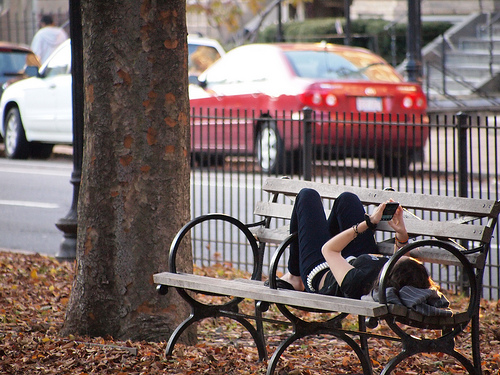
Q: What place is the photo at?
A: It is at the street.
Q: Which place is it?
A: It is a street.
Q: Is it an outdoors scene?
A: Yes, it is outdoors.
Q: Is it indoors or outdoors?
A: It is outdoors.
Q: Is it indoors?
A: No, it is outdoors.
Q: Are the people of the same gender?
A: No, they are both male and female.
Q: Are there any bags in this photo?
A: No, there are no bags.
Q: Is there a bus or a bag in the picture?
A: No, there are no bags or buses.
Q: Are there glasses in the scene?
A: No, there are no glasses.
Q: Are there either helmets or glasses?
A: No, there are no glasses or helmets.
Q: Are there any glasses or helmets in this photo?
A: No, there are no glasses or helmets.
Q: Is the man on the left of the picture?
A: Yes, the man is on the left of the image.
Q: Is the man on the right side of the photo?
A: No, the man is on the left of the image.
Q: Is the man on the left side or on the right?
A: The man is on the left of the image.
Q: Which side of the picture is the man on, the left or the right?
A: The man is on the left of the image.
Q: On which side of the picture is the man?
A: The man is on the left of the image.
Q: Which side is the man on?
A: The man is on the left of the image.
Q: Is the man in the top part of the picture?
A: Yes, the man is in the top of the image.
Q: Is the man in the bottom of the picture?
A: No, the man is in the top of the image.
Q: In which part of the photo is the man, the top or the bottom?
A: The man is in the top of the image.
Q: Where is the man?
A: The man is on the sidewalk.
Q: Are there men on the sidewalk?
A: Yes, there is a man on the sidewalk.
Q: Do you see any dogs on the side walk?
A: No, there is a man on the side walk.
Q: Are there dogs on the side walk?
A: No, there is a man on the side walk.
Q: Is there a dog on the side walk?
A: No, there is a man on the side walk.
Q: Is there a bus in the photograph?
A: No, there are no buses.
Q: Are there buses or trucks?
A: No, there are no buses or trucks.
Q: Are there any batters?
A: No, there are no batters.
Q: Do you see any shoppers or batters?
A: No, there are no batters or shoppers.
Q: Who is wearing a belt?
A: The girl is wearing a belt.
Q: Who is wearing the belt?
A: The girl is wearing a belt.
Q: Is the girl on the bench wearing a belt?
A: Yes, the girl is wearing a belt.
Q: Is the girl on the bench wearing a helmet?
A: No, the girl is wearing a belt.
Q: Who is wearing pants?
A: The girl is wearing pants.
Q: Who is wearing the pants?
A: The girl is wearing pants.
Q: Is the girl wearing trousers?
A: Yes, the girl is wearing trousers.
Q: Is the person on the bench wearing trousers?
A: Yes, the girl is wearing trousers.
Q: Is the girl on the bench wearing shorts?
A: No, the girl is wearing trousers.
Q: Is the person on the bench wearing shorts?
A: No, the girl is wearing trousers.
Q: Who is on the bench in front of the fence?
A: The girl is on the bench.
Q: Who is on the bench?
A: The girl is on the bench.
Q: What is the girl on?
A: The girl is on the bench.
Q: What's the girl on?
A: The girl is on the bench.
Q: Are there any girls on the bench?
A: Yes, there is a girl on the bench.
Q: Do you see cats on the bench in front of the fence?
A: No, there is a girl on the bench.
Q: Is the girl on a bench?
A: Yes, the girl is on a bench.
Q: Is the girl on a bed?
A: No, the girl is on a bench.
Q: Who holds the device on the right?
A: The girl holds the cell phone.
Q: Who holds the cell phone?
A: The girl holds the cell phone.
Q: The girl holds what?
A: The girl holds the cellphone.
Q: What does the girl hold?
A: The girl holds the cellphone.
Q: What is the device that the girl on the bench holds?
A: The device is a cell phone.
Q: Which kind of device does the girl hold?
A: The girl holds the mobile phone.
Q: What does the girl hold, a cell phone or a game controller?
A: The girl holds a cell phone.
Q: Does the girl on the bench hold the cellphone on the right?
A: Yes, the girl holds the cellphone.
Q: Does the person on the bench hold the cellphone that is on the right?
A: Yes, the girl holds the cellphone.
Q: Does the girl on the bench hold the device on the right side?
A: Yes, the girl holds the cellphone.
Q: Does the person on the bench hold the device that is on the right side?
A: Yes, the girl holds the cellphone.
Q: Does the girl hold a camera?
A: No, the girl holds the cellphone.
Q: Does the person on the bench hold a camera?
A: No, the girl holds the cellphone.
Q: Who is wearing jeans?
A: The girl is wearing jeans.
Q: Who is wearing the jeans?
A: The girl is wearing jeans.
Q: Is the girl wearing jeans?
A: Yes, the girl is wearing jeans.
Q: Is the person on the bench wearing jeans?
A: Yes, the girl is wearing jeans.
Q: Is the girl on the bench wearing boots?
A: No, the girl is wearing jeans.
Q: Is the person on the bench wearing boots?
A: No, the girl is wearing jeans.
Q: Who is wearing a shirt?
A: The girl is wearing a shirt.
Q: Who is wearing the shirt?
A: The girl is wearing a shirt.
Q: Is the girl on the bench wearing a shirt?
A: Yes, the girl is wearing a shirt.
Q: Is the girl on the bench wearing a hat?
A: No, the girl is wearing a shirt.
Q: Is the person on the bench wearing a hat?
A: No, the girl is wearing a shirt.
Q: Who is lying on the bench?
A: The girl is lying on the bench.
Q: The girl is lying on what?
A: The girl is lying on the bench.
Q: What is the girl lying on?
A: The girl is lying on the bench.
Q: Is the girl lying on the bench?
A: Yes, the girl is lying on the bench.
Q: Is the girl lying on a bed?
A: No, the girl is lying on the bench.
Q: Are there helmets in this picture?
A: No, there are no helmets.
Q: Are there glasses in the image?
A: No, there are no glasses.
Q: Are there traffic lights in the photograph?
A: No, there are no traffic lights.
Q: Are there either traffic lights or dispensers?
A: No, there are no traffic lights or dispensers.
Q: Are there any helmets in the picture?
A: No, there are no helmets.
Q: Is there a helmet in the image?
A: No, there are no helmets.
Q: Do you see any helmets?
A: No, there are no helmets.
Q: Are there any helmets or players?
A: No, there are no helmets or players.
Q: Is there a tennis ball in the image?
A: No, there are no tennis balls.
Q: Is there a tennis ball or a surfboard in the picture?
A: No, there are no tennis balls or surfboards.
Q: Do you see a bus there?
A: No, there are no buses.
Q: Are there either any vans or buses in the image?
A: No, there are no buses or vans.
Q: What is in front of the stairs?
A: The car is in front of the stairs.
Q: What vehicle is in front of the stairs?
A: The vehicle is a car.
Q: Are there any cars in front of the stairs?
A: Yes, there is a car in front of the stairs.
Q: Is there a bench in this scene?
A: Yes, there is a bench.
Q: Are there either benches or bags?
A: Yes, there is a bench.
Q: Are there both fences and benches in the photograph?
A: Yes, there are both a bench and a fence.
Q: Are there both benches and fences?
A: Yes, there are both a bench and a fence.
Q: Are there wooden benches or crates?
A: Yes, there is a wood bench.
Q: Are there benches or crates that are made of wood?
A: Yes, the bench is made of wood.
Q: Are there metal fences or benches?
A: Yes, there is a metal bench.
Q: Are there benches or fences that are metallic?
A: Yes, the bench is metallic.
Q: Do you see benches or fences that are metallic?
A: Yes, the bench is metallic.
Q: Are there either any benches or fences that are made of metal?
A: Yes, the bench is made of metal.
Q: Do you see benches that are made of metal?
A: Yes, there is a bench that is made of metal.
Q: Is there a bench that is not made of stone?
A: Yes, there is a bench that is made of metal.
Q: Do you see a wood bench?
A: Yes, there is a wood bench.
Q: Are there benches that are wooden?
A: Yes, there is a bench that is wooden.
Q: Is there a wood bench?
A: Yes, there is a bench that is made of wood.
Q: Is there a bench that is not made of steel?
A: Yes, there is a bench that is made of wood.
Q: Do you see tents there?
A: No, there are no tents.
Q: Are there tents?
A: No, there are no tents.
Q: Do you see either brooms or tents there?
A: No, there are no tents or brooms.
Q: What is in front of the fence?
A: The bench is in front of the fence.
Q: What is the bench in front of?
A: The bench is in front of the fence.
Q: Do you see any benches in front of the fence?
A: Yes, there is a bench in front of the fence.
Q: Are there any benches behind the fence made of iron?
A: No, the bench is in front of the fence.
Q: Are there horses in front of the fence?
A: No, there is a bench in front of the fence.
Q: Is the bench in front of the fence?
A: Yes, the bench is in front of the fence.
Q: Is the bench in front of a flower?
A: No, the bench is in front of the fence.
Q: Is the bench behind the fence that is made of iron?
A: No, the bench is in front of the fence.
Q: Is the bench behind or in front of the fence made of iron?
A: The bench is in front of the fence.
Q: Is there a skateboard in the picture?
A: No, there are no skateboards.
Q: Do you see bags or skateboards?
A: No, there are no skateboards or bags.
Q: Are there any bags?
A: No, there are no bags.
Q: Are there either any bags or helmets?
A: No, there are no bags or helmets.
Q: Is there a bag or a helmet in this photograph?
A: No, there are no bags or helmets.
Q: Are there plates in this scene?
A: Yes, there is a plate.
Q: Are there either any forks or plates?
A: Yes, there is a plate.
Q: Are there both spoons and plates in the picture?
A: No, there is a plate but no spoons.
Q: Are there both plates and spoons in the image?
A: No, there is a plate but no spoons.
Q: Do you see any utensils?
A: No, there are no utensils.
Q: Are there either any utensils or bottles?
A: No, there are no utensils or bottles.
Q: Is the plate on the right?
A: Yes, the plate is on the right of the image.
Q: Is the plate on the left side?
A: No, the plate is on the right of the image.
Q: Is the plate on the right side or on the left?
A: The plate is on the right of the image.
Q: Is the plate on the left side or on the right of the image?
A: The plate is on the right of the image.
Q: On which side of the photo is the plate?
A: The plate is on the right of the image.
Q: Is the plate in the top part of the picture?
A: Yes, the plate is in the top of the image.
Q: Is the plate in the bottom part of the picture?
A: No, the plate is in the top of the image.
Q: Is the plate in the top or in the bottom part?
A: The plate is in the top of the image.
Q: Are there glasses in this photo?
A: No, there are no glasses.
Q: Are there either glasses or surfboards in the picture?
A: No, there are no glasses or surfboards.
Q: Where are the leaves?
A: The leaves are on the ground.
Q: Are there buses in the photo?
A: No, there are no buses.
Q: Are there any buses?
A: No, there are no buses.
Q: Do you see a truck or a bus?
A: No, there are no buses or trucks.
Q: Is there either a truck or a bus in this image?
A: No, there are no buses or trucks.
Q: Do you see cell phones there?
A: Yes, there is a cell phone.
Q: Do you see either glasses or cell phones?
A: Yes, there is a cell phone.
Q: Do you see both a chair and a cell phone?
A: No, there is a cell phone but no chairs.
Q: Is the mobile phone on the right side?
A: Yes, the mobile phone is on the right of the image.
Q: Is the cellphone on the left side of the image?
A: No, the cellphone is on the right of the image.